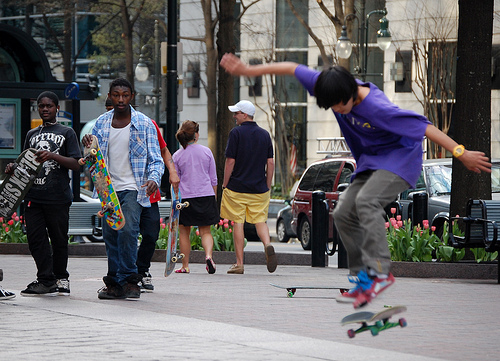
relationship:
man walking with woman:
[206, 96, 286, 272] [166, 120, 222, 269]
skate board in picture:
[267, 282, 346, 298] [12, 2, 483, 358]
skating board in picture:
[163, 186, 188, 277] [12, 2, 483, 358]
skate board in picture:
[79, 135, 128, 230] [12, 2, 483, 358]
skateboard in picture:
[1, 145, 47, 234] [12, 2, 483, 358]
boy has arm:
[219, 55, 485, 311] [392, 106, 462, 157]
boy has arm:
[219, 55, 485, 311] [248, 60, 312, 88]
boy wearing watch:
[219, 55, 485, 311] [450, 145, 464, 159]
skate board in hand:
[79, 135, 129, 234] [79, 134, 96, 146]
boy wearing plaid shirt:
[85, 75, 167, 303] [92, 105, 164, 206]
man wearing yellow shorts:
[218, 99, 278, 274] [221, 188, 271, 222]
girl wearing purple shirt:
[170, 121, 220, 275] [172, 144, 217, 197]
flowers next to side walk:
[382, 205, 442, 263] [343, 280, 481, 359]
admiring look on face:
[111, 91, 130, 106] [112, 86, 129, 114]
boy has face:
[85, 75, 167, 303] [112, 86, 129, 114]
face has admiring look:
[112, 86, 129, 114] [111, 91, 130, 106]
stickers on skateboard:
[4, 178, 22, 203] [4, 145, 51, 226]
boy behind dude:
[85, 75, 167, 303] [93, 74, 167, 301]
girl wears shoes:
[170, 120, 219, 275] [173, 253, 222, 276]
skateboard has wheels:
[333, 302, 413, 342] [346, 320, 407, 341]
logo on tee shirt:
[342, 114, 382, 132] [291, 63, 431, 187]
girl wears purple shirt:
[170, 120, 219, 275] [169, 144, 216, 196]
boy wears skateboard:
[90, 73, 170, 309] [77, 133, 131, 240]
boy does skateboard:
[215, 51, 494, 310] [336, 304, 412, 341]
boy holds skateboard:
[15, 87, 89, 299] [1, 134, 48, 235]